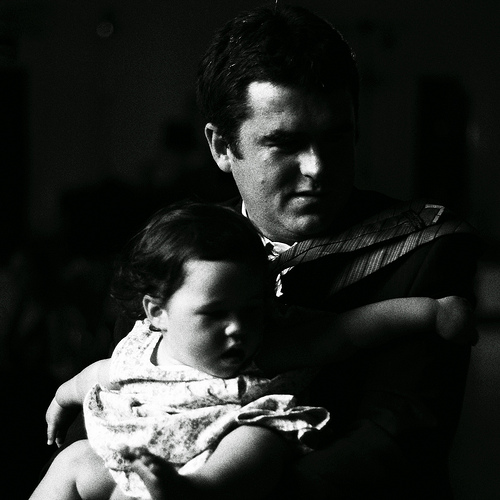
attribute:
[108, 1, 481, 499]
man — looking hard, looking, father, adult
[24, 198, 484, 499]
child — held, reaching, looking, young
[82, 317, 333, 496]
dress — wrinkled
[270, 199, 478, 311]
tie — striped, dark, blowing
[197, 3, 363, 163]
hair — black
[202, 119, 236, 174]
ear — right ear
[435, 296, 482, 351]
hand — reaching